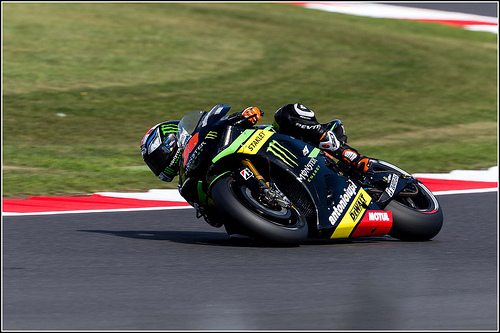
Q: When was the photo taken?
A: Daytime.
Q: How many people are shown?
A: One.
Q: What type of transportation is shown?
A: Motorcycle.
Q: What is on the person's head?
A: Helmet.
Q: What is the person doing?
A: Riding.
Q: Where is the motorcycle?
A: Pavement.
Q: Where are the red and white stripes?
A: Side of pavement.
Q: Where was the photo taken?
A: At a race.